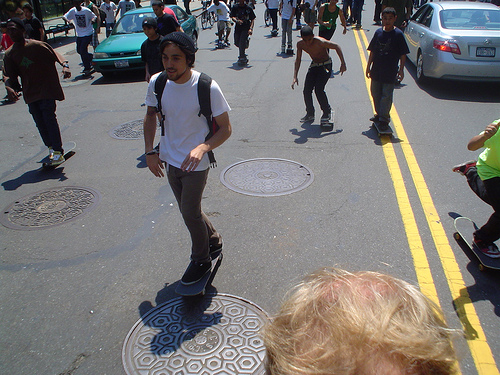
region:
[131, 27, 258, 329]
The man is standing.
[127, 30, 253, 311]
Man on a skateboard.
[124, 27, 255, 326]
Man is wearing cap.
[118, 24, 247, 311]
The cap is black.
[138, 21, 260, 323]
Man is carrying backpack.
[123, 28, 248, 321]
Man is wearing shirt.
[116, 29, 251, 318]
Man's shirt is white.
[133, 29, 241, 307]
Man is wearing pants.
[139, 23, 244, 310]
Man's pants are tan.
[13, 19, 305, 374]
Man is on street.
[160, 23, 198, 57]
a navy hat on a man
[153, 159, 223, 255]
gray pants on a man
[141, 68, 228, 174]
a white shirt on a man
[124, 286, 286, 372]
a man hole cover in a road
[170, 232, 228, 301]
a gray skateboard under a man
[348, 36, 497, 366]
a double yellow line down a road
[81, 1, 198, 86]
a blue car in the road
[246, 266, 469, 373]
blond hair on a head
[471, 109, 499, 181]
a yellow shirt on a person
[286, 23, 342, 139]
a shirtless boy on a skateboard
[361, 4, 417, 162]
The boy is on a skateboard.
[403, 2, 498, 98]
The car is gray.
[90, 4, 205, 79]
The car is blue.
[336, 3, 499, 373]
Painted lines on street.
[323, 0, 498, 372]
Painted lines are yellow.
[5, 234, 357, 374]
Manhole cover in street.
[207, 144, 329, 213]
Manhole cover is round.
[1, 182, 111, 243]
Manhole cover is metal.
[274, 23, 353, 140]
Boy is wearing cap.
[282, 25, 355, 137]
The boy is shirtless.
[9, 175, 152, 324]
the ground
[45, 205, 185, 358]
the ground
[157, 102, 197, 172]
man wearing a white shirt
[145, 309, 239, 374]
the top of the sewer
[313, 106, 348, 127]
man riding a skateboard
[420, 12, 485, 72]
a car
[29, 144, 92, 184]
man riding a skateboard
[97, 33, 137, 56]
a green car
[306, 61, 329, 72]
man wearing a belt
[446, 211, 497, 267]
a skateboard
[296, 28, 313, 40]
man wearing a hat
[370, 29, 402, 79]
man wearing a blue shirt